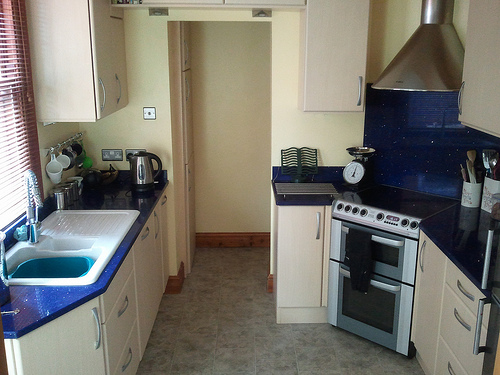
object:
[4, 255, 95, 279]
tub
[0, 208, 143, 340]
sink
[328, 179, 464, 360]
dutch oven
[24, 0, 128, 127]
cabinets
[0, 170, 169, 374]
counter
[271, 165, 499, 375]
counter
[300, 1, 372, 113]
cabinets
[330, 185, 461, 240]
stove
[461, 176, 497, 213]
mugs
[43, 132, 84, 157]
rod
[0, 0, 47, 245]
window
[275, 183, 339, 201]
table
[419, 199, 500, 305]
table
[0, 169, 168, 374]
table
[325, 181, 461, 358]
oven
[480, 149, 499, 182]
utensils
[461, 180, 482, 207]
canister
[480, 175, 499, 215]
canister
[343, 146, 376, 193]
scale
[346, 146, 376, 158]
dial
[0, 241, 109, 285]
bucket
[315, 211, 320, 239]
handle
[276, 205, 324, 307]
cabinet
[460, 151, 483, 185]
utensils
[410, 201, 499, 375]
counter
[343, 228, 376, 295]
towel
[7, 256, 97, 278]
plastic bin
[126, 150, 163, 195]
kettle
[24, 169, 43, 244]
faucett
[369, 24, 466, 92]
exhaust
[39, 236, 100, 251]
sink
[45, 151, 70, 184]
cups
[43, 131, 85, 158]
rack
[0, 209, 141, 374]
cabinet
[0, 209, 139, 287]
sink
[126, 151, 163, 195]
pot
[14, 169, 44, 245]
faucet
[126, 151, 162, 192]
coffee carafe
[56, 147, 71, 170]
cup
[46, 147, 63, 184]
cup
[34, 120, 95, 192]
wall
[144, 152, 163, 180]
handle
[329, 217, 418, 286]
oven door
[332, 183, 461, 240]
dials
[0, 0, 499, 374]
kitchen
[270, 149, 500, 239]
corner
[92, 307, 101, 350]
handle